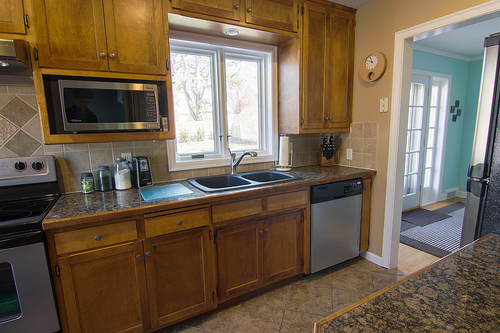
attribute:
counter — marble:
[50, 173, 194, 214]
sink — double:
[188, 163, 301, 195]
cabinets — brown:
[221, 197, 309, 301]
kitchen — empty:
[32, 14, 464, 227]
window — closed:
[165, 35, 273, 155]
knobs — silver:
[96, 48, 123, 63]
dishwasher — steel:
[313, 179, 359, 265]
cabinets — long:
[299, 3, 352, 131]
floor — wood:
[397, 240, 441, 273]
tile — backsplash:
[3, 94, 39, 154]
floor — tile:
[215, 275, 370, 322]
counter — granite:
[317, 272, 498, 330]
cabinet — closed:
[246, 2, 295, 31]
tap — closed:
[250, 146, 260, 159]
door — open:
[387, 19, 499, 274]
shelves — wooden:
[158, 0, 300, 33]